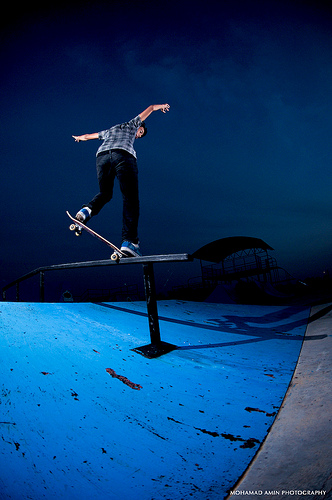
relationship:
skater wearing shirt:
[66, 104, 170, 261] [95, 115, 143, 160]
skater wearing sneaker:
[66, 104, 170, 261] [73, 201, 95, 227]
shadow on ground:
[215, 309, 326, 337] [12, 301, 282, 498]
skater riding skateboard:
[66, 104, 170, 261] [64, 207, 128, 260]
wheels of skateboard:
[69, 223, 85, 237] [61, 208, 128, 263]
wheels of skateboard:
[69, 223, 82, 236] [66, 214, 127, 260]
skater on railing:
[52, 120, 158, 237] [55, 237, 236, 290]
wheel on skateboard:
[109, 252, 121, 261] [64, 207, 128, 260]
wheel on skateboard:
[68, 222, 76, 230] [62, 207, 122, 259]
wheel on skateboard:
[111, 253, 119, 261] [62, 207, 122, 259]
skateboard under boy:
[61, 205, 126, 257] [68, 98, 171, 260]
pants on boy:
[79, 147, 140, 250] [68, 98, 171, 260]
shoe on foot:
[72, 204, 92, 227] [75, 208, 91, 223]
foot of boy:
[75, 208, 91, 223] [68, 98, 171, 260]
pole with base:
[141, 267, 159, 346] [127, 338, 180, 360]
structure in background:
[186, 231, 298, 298] [279, 241, 300, 263]